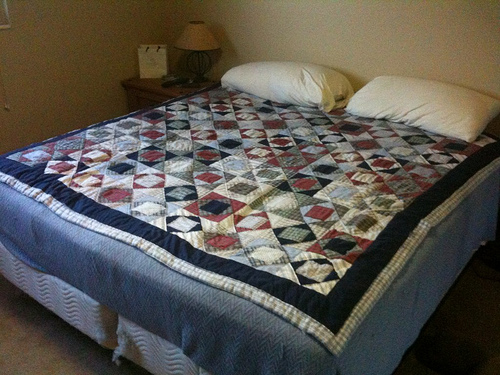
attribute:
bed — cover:
[114, 90, 404, 265]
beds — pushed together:
[4, 77, 496, 374]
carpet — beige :
[1, 272, 159, 373]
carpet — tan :
[0, 277, 142, 374]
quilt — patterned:
[4, 45, 498, 339]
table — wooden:
[121, 59, 236, 123]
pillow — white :
[352, 67, 498, 142]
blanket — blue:
[1, 85, 497, 370]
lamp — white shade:
[166, 17, 223, 97]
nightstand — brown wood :
[123, 74, 212, 109]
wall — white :
[240, 0, 498, 94]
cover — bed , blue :
[121, 80, 421, 271]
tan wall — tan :
[169, 0, 497, 150]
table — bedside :
[122, 74, 217, 114]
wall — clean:
[33, 7, 103, 107]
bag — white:
[135, 30, 173, 78]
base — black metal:
[187, 50, 208, 81]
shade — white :
[174, 20, 223, 58]